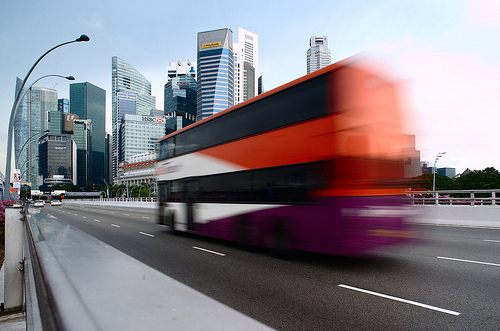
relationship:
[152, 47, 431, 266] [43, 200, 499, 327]
bus driving on lanes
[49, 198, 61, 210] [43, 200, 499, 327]
car driving on lanes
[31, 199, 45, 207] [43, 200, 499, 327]
car driving on lanes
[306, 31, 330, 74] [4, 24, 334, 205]
building in city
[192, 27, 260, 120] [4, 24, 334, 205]
angled building in city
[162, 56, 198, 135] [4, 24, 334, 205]
building in city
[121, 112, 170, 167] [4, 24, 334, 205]
building in city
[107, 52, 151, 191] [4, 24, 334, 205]
building in city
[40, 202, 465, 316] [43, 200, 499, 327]
lines painted on lanes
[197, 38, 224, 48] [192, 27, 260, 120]
sign on angled building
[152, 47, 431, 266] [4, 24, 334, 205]
bus driving toward city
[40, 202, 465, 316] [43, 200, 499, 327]
lines dividing lanes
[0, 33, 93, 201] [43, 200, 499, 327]
curved lampposts on lanes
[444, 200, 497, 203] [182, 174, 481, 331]
rails built on side of street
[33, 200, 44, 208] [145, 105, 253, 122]
car driving into a city